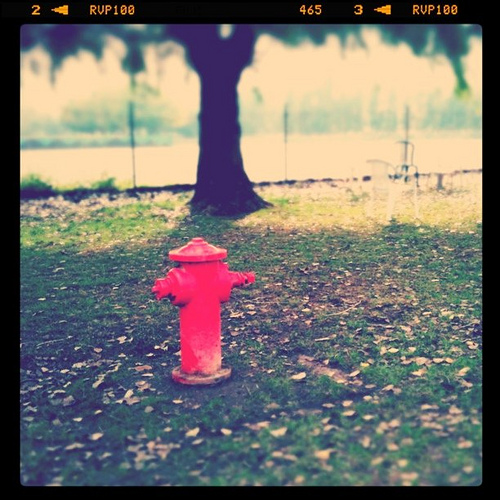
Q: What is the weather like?
A: It is clear.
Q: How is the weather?
A: It is clear.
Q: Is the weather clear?
A: Yes, it is clear.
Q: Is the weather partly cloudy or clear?
A: It is clear.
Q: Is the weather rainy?
A: No, it is clear.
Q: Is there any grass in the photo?
A: Yes, there is grass.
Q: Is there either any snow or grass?
A: Yes, there is grass.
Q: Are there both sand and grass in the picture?
A: No, there is grass but no sand.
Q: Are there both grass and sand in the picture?
A: No, there is grass but no sand.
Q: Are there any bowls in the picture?
A: No, there are no bowls.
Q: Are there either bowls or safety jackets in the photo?
A: No, there are no bowls or safety jackets.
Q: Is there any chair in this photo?
A: Yes, there is a chair.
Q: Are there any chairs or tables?
A: Yes, there is a chair.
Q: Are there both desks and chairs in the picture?
A: No, there is a chair but no desks.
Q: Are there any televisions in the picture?
A: No, there are no televisions.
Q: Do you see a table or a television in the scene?
A: No, there are no televisions or tables.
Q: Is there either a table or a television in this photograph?
A: No, there are no televisions or tables.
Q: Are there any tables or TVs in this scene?
A: No, there are no TVs or tables.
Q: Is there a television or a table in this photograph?
A: No, there are no televisions or tables.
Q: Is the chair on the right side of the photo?
A: Yes, the chair is on the right of the image.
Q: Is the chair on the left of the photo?
A: No, the chair is on the right of the image.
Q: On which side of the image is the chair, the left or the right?
A: The chair is on the right of the image.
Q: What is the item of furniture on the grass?
A: The piece of furniture is a chair.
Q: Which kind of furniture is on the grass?
A: The piece of furniture is a chair.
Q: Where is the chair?
A: The chair is on the grass.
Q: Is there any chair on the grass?
A: Yes, there is a chair on the grass.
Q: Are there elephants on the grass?
A: No, there is a chair on the grass.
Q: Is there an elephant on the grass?
A: No, there is a chair on the grass.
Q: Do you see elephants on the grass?
A: No, there is a chair on the grass.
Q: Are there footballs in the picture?
A: No, there are no footballs.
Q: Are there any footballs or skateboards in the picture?
A: No, there are no footballs or skateboards.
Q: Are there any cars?
A: No, there are no cars.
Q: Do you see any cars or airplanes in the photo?
A: No, there are no cars or airplanes.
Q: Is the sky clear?
A: Yes, the sky is clear.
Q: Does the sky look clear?
A: Yes, the sky is clear.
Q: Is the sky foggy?
A: No, the sky is clear.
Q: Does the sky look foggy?
A: No, the sky is clear.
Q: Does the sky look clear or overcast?
A: The sky is clear.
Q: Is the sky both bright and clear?
A: Yes, the sky is bright and clear.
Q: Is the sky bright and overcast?
A: No, the sky is bright but clear.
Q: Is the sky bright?
A: Yes, the sky is bright.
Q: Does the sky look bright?
A: Yes, the sky is bright.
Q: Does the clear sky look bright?
A: Yes, the sky is bright.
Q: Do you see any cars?
A: No, there are no cars.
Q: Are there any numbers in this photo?
A: Yes, there are numbers.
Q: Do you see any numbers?
A: Yes, there are numbers.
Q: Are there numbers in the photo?
A: Yes, there are numbers.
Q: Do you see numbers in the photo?
A: Yes, there are numbers.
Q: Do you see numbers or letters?
A: Yes, there are numbers.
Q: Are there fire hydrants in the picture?
A: Yes, there is a fire hydrant.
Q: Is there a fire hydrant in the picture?
A: Yes, there is a fire hydrant.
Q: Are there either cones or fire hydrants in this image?
A: Yes, there is a fire hydrant.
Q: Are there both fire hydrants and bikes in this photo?
A: No, there is a fire hydrant but no bikes.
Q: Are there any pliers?
A: No, there are no pliers.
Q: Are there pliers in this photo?
A: No, there are no pliers.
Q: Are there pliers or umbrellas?
A: No, there are no pliers or umbrellas.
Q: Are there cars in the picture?
A: No, there are no cars.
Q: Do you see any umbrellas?
A: No, there are no umbrellas.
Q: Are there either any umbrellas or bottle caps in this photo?
A: No, there are no umbrellas or bottle caps.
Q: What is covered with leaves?
A: The ground is covered with leaves.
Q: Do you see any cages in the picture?
A: No, there are no cages.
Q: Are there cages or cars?
A: No, there are no cages or cars.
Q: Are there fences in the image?
A: Yes, there is a fence.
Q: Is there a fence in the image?
A: Yes, there is a fence.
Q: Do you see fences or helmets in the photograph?
A: Yes, there is a fence.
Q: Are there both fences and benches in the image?
A: No, there is a fence but no benches.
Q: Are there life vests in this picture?
A: No, there are no life vests.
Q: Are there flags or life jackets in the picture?
A: No, there are no life jackets or flags.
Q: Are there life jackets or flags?
A: No, there are no life jackets or flags.